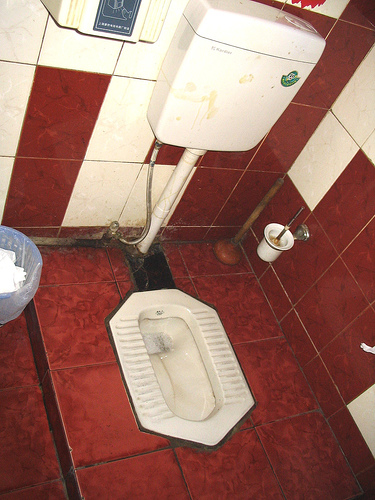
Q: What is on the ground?
A: A toilet.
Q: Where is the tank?
A: On the wall.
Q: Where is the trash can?
A: Next to the toilet.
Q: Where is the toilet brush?
A: Next to the plunger.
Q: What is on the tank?
A: Stains.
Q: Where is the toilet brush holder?
A: On the wall.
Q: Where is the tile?
A: On the floor and the walls.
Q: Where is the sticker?
A: On the tank.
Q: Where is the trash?
A: In the trash can.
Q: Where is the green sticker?
A: On toilet tank.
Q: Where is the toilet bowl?
A: In ground.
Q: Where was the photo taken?
A: Bathroom.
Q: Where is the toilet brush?
A: In white holder.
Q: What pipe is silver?
A: Metal pipe.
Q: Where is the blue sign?
A: White box on the wall.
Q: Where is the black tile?
A: Behind toilet bowl.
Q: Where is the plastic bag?
A: In blue trash can.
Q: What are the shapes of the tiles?
A: Square.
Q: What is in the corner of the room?
A: A plunger.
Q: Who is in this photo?
A: No one.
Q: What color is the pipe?
A: White.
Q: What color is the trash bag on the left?
A: Blue.